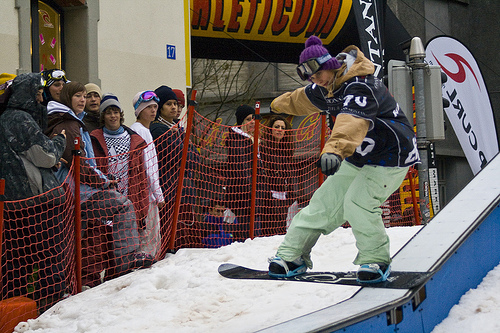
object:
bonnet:
[297, 36, 341, 82]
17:
[166, 44, 176, 60]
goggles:
[132, 91, 163, 111]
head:
[131, 92, 162, 123]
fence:
[7, 90, 418, 333]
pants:
[275, 156, 410, 270]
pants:
[76, 188, 138, 267]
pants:
[6, 189, 73, 314]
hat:
[236, 104, 255, 129]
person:
[232, 96, 262, 243]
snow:
[12, 227, 498, 332]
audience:
[2, 62, 299, 314]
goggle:
[297, 55, 333, 81]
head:
[295, 41, 336, 86]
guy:
[267, 36, 423, 282]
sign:
[195, 0, 342, 37]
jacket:
[269, 45, 424, 168]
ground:
[5, 221, 497, 331]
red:
[191, 1, 341, 36]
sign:
[357, 0, 386, 66]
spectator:
[0, 68, 77, 316]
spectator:
[38, 67, 68, 104]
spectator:
[77, 84, 105, 132]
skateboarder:
[218, 262, 433, 291]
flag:
[385, 34, 500, 175]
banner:
[191, 0, 357, 45]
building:
[120, 124, 497, 209]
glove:
[314, 151, 342, 176]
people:
[92, 93, 156, 272]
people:
[129, 89, 167, 259]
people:
[149, 85, 192, 252]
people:
[228, 103, 264, 239]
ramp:
[31, 92, 484, 329]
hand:
[316, 153, 338, 174]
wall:
[7, 9, 253, 228]